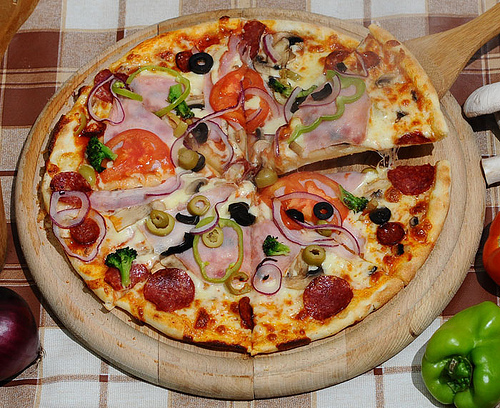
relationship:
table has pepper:
[0, 1, 499, 406] [421, 300, 499, 407]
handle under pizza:
[402, 2, 500, 100] [264, 25, 438, 186]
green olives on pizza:
[79, 165, 94, 183] [39, 17, 452, 353]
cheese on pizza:
[118, 59, 384, 294] [39, 17, 452, 353]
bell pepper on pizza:
[419, 297, 497, 406] [39, 17, 452, 353]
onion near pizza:
[2, 282, 43, 403] [39, 17, 452, 353]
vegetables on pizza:
[165, 82, 192, 119] [39, 17, 452, 353]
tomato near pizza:
[480, 210, 499, 285] [39, 17, 452, 353]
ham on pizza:
[119, 79, 168, 130] [34, 2, 474, 364]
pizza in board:
[37, 15, 452, 356] [15, 6, 487, 400]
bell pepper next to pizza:
[419, 299, 500, 407] [64, 40, 409, 348]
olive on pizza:
[164, 116, 246, 200] [37, 15, 452, 356]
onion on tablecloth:
[0, 285, 44, 384] [1, 1, 498, 406]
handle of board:
[395, 17, 492, 99] [10, 6, 484, 402]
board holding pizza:
[10, 6, 484, 402] [39, 17, 452, 353]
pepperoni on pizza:
[142, 265, 196, 313] [39, 17, 452, 353]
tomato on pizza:
[96, 125, 178, 195] [39, 17, 452, 353]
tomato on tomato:
[204, 64, 279, 136] [96, 125, 178, 195]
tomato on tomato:
[262, 162, 369, 239] [96, 125, 178, 195]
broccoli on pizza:
[107, 247, 134, 282] [39, 17, 452, 353]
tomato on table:
[209, 66, 272, 133] [0, 1, 499, 406]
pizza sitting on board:
[37, 15, 452, 356] [15, 6, 487, 400]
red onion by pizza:
[271, 191, 363, 253] [39, 17, 452, 353]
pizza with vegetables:
[39, 17, 452, 353] [167, 83, 196, 119]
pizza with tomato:
[39, 17, 452, 353] [92, 127, 173, 192]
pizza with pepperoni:
[39, 17, 452, 353] [385, 161, 430, 196]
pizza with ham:
[39, 17, 452, 353] [295, 75, 371, 147]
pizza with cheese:
[39, 17, 452, 353] [364, 91, 397, 146]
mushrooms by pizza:
[147, 89, 259, 196] [34, 2, 474, 364]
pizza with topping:
[37, 15, 452, 356] [138, 52, 365, 265]